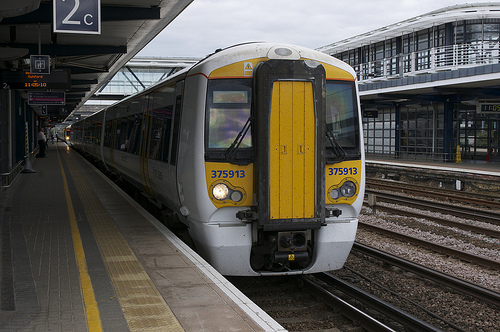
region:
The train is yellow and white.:
[190, 48, 382, 294]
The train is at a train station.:
[50, 71, 400, 309]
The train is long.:
[68, 49, 360, 280]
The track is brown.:
[222, 175, 489, 329]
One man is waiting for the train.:
[14, 122, 141, 327]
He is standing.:
[33, 117, 70, 185]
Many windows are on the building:
[320, 18, 496, 91]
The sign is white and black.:
[43, 2, 113, 44]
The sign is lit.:
[11, 63, 58, 97]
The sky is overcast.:
[181, 8, 361, 70]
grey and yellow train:
[64, 15, 398, 294]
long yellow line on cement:
[42, 137, 114, 322]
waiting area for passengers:
[6, 128, 247, 316]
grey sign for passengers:
[31, 3, 120, 47]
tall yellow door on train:
[245, 55, 341, 238]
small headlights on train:
[192, 166, 375, 208]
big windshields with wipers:
[181, 58, 408, 167]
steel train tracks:
[248, 161, 495, 318]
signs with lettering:
[11, 30, 93, 134]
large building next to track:
[305, 16, 496, 187]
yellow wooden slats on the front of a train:
[271, 83, 313, 221]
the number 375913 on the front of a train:
[210, 164, 246, 184]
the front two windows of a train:
[217, 82, 357, 154]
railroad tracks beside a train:
[387, 162, 487, 327]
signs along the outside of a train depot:
[19, 47, 66, 114]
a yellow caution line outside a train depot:
[56, 155, 100, 327]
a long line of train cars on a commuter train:
[72, 90, 194, 190]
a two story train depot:
[360, 17, 496, 172]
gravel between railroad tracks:
[420, 247, 451, 266]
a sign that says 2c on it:
[56, 0, 100, 37]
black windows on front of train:
[206, 82, 369, 164]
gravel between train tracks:
[378, 192, 497, 307]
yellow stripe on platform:
[51, 145, 101, 330]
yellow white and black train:
[92, 36, 372, 273]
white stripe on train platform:
[77, 143, 259, 322]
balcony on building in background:
[332, 30, 497, 80]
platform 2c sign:
[47, 0, 106, 33]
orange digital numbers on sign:
[25, 71, 56, 91]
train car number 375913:
[202, 164, 253, 183]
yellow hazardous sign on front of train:
[242, 57, 255, 77]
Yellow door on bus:
[263, 76, 335, 226]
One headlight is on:
[211, 180, 227, 210]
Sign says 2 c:
[51, 1, 109, 40]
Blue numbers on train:
[206, 163, 253, 187]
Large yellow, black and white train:
[70, 36, 368, 288]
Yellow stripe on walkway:
[53, 136, 112, 331]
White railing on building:
[355, 40, 499, 72]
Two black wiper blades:
[228, 109, 360, 169]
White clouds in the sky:
[185, 0, 436, 53]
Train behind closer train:
[63, 121, 73, 146]